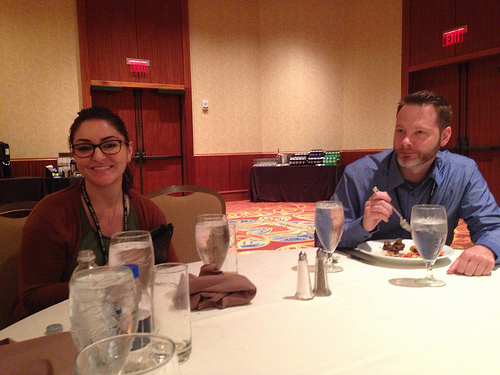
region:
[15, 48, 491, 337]
A man and a woman at the dining table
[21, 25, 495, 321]
Lunch time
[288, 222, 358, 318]
Salt and pepper shakers on the table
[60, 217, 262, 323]
Ice cold water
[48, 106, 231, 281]
A woman wearing prescription glasses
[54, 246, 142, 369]
Ice in the water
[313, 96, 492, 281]
A man in bule shirt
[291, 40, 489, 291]
A man having a lunch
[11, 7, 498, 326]
A man and a woman during the lunch hour at the conference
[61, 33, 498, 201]
Two doors with exit sign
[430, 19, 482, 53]
An exit sign is over the door.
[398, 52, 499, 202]
A pair of doors in the background.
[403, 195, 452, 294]
A glass.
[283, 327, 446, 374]
The table top is white.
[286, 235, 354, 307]
A salt and pepper shaker.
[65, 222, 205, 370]
A lot of glasses.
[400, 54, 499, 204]
The doors are made of wood.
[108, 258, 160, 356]
A plastic bottle.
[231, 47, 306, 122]
The walls are off white.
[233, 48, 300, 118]
The walls have a pattern on them.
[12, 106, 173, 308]
Lady sitting at dining table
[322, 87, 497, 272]
Man eating at dining table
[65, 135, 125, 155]
Glasses on lady at dining table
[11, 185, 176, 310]
Burgundy sweater on lady at table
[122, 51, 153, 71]
Red "exit" sign at large meeting room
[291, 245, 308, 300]
Salt shaker on dining table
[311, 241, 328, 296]
Pepper shaker on dining table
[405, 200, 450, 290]
Water glass on dining table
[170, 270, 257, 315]
Brown napkin on dining table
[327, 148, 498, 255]
Blue shirt on man dining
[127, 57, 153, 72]
sign above the doors.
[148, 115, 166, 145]
wooden panel on the door.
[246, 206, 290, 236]
carpet on the floor.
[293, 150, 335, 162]
soda on the table.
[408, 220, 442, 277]
glass of water on the table.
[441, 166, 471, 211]
blue shirt on man.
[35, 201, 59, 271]
red sweater on woman.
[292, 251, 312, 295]
salt on the table.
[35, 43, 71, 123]
wallpaper on the wall.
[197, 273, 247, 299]
napkin on the table.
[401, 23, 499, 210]
exit sign over two doors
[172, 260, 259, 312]
rumpled cloth dinner napkin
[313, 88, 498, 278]
man holding a fork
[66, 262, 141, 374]
full glass of ice water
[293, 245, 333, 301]
glass salt and pepper shakers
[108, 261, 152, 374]
plastic water container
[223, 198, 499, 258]
brightly colored wall to wall carpet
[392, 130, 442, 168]
partially gray beard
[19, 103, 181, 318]
smiling woman wearing glasses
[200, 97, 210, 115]
climate control thermostat